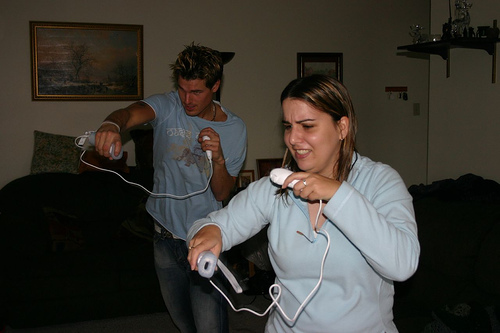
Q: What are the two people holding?
A: Wii Remotes.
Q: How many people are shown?
A: Two.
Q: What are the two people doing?
A: Playing Wii.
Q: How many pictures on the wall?
A: Two.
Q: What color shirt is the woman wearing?
A: Blue.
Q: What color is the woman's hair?
A: Brown.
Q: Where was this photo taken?
A: In a home.